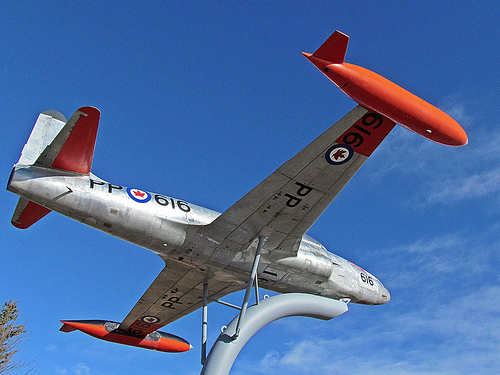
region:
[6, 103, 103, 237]
the tale of a plane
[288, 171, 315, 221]
two P's in black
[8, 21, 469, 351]
a silver and red plane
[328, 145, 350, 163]
a red leaf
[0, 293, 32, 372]
brown tree leafs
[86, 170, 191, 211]
writing on the side of a plane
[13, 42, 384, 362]
a plane attached to a metal beam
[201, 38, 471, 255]
wing of a plane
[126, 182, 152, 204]
blue circle around a leaf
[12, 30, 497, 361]
an almost clear sky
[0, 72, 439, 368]
model plane on display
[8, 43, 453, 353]
plane with red details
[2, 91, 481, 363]
plane number is pp616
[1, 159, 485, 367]
silver plane with red details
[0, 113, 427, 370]
plane suspended in air by metal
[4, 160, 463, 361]
plane has maple leaf detail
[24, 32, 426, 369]
plane with red barrels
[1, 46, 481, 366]
plane with black writing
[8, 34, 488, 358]
plane with red maple leaf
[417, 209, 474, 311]
blue sky and white cirrus clouds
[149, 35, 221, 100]
blue sky on top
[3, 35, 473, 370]
a flight with orange and white color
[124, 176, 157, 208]
a flight with canada flag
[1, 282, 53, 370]
dry trees next to the flight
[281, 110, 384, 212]
a flight with written numbers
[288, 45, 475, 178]
a flight with orange color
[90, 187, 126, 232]
a flight with white color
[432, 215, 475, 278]
white clouds on sky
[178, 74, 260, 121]
a blue sky on air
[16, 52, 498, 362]
a flight on air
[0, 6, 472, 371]
the plane is silver and orange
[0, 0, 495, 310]
the sky is blue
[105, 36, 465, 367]
the wings have pp on them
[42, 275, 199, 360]
the tips of the wings are orange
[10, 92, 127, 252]
the tail is orange and silver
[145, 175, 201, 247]
the plane has 616 on it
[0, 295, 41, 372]
the tree is green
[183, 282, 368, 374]
the pole is gray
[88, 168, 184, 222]
the plane has a red, white, and blue symbol on it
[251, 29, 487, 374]
the sky has clouds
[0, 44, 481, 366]
a vintage airplane is mounted on a pole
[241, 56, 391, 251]
right wing of airplane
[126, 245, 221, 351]
left wing of airplane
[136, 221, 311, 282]
belly of airplane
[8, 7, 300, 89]
clear blue sky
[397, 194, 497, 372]
thin wisps of cloud seen in sky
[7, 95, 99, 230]
tail of the airplane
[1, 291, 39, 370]
top part of a tree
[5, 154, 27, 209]
exhaust of airplane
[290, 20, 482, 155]
torpedo's on wing tip of plane